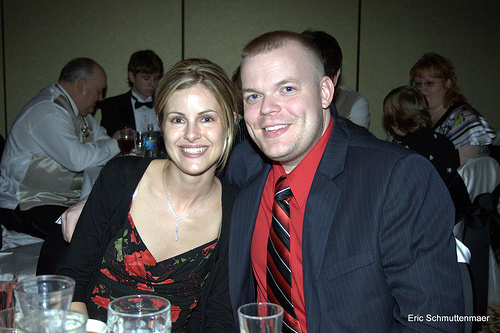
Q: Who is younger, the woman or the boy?
A: The boy is younger than the woman.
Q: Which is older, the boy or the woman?
A: The woman is older than the boy.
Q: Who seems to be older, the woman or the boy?
A: The woman is older than the boy.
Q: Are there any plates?
A: No, there are no plates.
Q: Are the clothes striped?
A: Yes, the clothes are striped.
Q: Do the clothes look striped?
A: Yes, the clothes are striped.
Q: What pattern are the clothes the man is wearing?
A: The clothes are striped.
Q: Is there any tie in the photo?
A: Yes, there is a tie.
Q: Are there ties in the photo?
A: Yes, there is a tie.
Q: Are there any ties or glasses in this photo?
A: Yes, there is a tie.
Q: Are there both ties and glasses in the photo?
A: Yes, there are both a tie and glasses.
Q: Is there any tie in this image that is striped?
A: Yes, there is a striped tie.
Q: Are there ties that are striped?
A: Yes, there is a tie that is striped.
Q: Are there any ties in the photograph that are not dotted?
A: Yes, there is a striped tie.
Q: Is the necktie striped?
A: Yes, the necktie is striped.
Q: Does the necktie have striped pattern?
A: Yes, the necktie is striped.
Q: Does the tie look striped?
A: Yes, the tie is striped.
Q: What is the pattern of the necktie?
A: The necktie is striped.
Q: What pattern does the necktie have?
A: The necktie has striped pattern.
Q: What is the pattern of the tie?
A: The necktie is striped.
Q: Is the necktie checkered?
A: No, the necktie is striped.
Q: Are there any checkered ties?
A: No, there is a tie but it is striped.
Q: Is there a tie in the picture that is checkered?
A: No, there is a tie but it is striped.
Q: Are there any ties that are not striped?
A: No, there is a tie but it is striped.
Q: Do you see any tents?
A: No, there are no tents.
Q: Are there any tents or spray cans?
A: No, there are no tents or spray cans.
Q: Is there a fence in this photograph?
A: No, there are no fences.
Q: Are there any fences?
A: No, there are no fences.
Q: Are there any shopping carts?
A: No, there are no shopping carts.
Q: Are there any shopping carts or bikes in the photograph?
A: No, there are no shopping carts or bikes.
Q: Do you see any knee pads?
A: No, there are no knee pads.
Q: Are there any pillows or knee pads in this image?
A: No, there are no knee pads or pillows.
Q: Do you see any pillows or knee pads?
A: No, there are no knee pads or pillows.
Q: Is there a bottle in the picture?
A: Yes, there is a bottle.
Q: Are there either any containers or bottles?
A: Yes, there is a bottle.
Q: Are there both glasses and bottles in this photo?
A: Yes, there are both a bottle and glasses.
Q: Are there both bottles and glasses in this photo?
A: Yes, there are both a bottle and glasses.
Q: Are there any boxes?
A: No, there are no boxes.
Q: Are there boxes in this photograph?
A: No, there are no boxes.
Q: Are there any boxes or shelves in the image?
A: No, there are no boxes or shelves.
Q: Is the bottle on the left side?
A: Yes, the bottle is on the left of the image.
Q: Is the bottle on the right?
A: No, the bottle is on the left of the image.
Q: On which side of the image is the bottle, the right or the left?
A: The bottle is on the left of the image.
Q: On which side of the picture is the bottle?
A: The bottle is on the left of the image.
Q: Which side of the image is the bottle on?
A: The bottle is on the left of the image.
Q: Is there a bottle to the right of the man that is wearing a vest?
A: Yes, there is a bottle to the right of the man.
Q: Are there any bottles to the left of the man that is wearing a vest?
A: No, the bottle is to the right of the man.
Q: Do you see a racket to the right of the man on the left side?
A: No, there is a bottle to the right of the man.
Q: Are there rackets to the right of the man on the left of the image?
A: No, there is a bottle to the right of the man.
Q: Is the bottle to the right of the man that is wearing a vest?
A: Yes, the bottle is to the right of the man.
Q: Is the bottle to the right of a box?
A: No, the bottle is to the right of the man.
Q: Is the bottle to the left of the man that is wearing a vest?
A: No, the bottle is to the right of the man.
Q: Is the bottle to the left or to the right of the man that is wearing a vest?
A: The bottle is to the right of the man.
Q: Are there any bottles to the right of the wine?
A: Yes, there is a bottle to the right of the wine.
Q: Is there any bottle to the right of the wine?
A: Yes, there is a bottle to the right of the wine.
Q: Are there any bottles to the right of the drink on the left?
A: Yes, there is a bottle to the right of the wine.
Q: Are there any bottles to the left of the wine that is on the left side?
A: No, the bottle is to the right of the wine.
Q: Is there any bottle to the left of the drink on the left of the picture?
A: No, the bottle is to the right of the wine.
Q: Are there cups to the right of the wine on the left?
A: No, there is a bottle to the right of the wine.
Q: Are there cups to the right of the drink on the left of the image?
A: No, there is a bottle to the right of the wine.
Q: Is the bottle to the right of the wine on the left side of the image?
A: Yes, the bottle is to the right of the wine.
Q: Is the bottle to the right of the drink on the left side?
A: Yes, the bottle is to the right of the wine.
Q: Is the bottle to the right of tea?
A: No, the bottle is to the right of the wine.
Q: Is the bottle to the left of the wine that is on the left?
A: No, the bottle is to the right of the wine.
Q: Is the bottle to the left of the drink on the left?
A: No, the bottle is to the right of the wine.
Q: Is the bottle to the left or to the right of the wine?
A: The bottle is to the right of the wine.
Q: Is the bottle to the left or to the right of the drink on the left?
A: The bottle is to the right of the wine.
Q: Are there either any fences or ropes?
A: No, there are no fences or ropes.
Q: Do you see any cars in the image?
A: No, there are no cars.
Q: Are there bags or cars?
A: No, there are no cars or bags.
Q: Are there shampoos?
A: No, there are no shampoos.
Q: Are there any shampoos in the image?
A: No, there are no shampoos.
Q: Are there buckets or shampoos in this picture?
A: No, there are no shampoos or buckets.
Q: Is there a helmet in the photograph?
A: No, there are no helmets.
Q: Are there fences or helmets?
A: No, there are no helmets or fences.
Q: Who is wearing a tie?
A: The man is wearing a tie.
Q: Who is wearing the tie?
A: The man is wearing a tie.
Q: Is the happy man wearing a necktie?
A: Yes, the man is wearing a necktie.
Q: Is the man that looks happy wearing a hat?
A: No, the man is wearing a necktie.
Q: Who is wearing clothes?
A: The man is wearing clothes.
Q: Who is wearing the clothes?
A: The man is wearing clothes.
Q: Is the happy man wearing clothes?
A: Yes, the man is wearing clothes.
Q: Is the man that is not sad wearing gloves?
A: No, the man is wearing clothes.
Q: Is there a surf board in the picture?
A: No, there are no surfboards.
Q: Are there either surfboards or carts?
A: No, there are no surfboards or carts.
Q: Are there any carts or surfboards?
A: No, there are no surfboards or carts.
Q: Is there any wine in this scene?
A: Yes, there is wine.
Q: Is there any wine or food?
A: Yes, there is wine.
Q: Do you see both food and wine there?
A: No, there is wine but no food.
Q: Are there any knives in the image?
A: No, there are no knives.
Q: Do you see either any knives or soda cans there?
A: No, there are no knives or soda cans.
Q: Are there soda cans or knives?
A: No, there are no knives or soda cans.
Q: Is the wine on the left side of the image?
A: Yes, the wine is on the left of the image.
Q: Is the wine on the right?
A: No, the wine is on the left of the image.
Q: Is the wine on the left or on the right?
A: The wine is on the left of the image.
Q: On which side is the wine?
A: The wine is on the left of the image.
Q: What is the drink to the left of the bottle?
A: The drink is wine.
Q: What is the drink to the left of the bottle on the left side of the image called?
A: The drink is wine.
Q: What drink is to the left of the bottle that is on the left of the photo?
A: The drink is wine.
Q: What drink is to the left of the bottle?
A: The drink is wine.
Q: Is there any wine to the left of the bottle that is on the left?
A: Yes, there is wine to the left of the bottle.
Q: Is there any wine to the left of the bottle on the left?
A: Yes, there is wine to the left of the bottle.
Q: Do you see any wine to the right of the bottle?
A: No, the wine is to the left of the bottle.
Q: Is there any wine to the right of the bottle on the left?
A: No, the wine is to the left of the bottle.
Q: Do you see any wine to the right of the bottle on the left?
A: No, the wine is to the left of the bottle.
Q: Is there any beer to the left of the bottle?
A: No, there is wine to the left of the bottle.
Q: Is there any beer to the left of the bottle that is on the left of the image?
A: No, there is wine to the left of the bottle.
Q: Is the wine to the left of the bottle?
A: Yes, the wine is to the left of the bottle.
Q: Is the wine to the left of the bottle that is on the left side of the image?
A: Yes, the wine is to the left of the bottle.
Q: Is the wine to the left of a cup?
A: No, the wine is to the left of the bottle.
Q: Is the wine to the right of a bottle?
A: No, the wine is to the left of a bottle.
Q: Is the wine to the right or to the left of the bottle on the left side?
A: The wine is to the left of the bottle.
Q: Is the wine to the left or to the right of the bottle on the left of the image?
A: The wine is to the left of the bottle.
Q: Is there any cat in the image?
A: No, there are no cats.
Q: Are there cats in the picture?
A: No, there are no cats.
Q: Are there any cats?
A: No, there are no cats.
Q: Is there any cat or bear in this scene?
A: No, there are no cats or bears.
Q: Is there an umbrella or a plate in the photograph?
A: No, there are no plates or umbrellas.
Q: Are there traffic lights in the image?
A: No, there are no traffic lights.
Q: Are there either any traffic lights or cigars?
A: No, there are no traffic lights or cigars.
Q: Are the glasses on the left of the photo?
A: Yes, the glasses are on the left of the image.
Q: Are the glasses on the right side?
A: No, the glasses are on the left of the image.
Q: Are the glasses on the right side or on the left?
A: The glasses are on the left of the image.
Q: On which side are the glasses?
A: The glasses are on the left of the image.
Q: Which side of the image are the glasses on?
A: The glasses are on the left of the image.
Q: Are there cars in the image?
A: No, there are no cars.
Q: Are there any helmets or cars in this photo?
A: No, there are no cars or helmets.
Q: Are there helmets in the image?
A: No, there are no helmets.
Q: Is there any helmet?
A: No, there are no helmets.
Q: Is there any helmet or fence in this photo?
A: No, there are no helmets or fences.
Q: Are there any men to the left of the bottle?
A: Yes, there is a man to the left of the bottle.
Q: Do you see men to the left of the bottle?
A: Yes, there is a man to the left of the bottle.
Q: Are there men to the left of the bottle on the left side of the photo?
A: Yes, there is a man to the left of the bottle.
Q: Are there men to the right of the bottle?
A: No, the man is to the left of the bottle.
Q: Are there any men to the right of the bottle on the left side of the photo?
A: No, the man is to the left of the bottle.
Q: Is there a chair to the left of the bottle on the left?
A: No, there is a man to the left of the bottle.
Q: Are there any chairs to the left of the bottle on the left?
A: No, there is a man to the left of the bottle.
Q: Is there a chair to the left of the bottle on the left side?
A: No, there is a man to the left of the bottle.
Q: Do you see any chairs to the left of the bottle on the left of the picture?
A: No, there is a man to the left of the bottle.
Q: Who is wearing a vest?
A: The man is wearing a vest.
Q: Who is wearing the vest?
A: The man is wearing a vest.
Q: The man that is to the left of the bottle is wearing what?
A: The man is wearing a vest.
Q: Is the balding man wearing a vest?
A: Yes, the man is wearing a vest.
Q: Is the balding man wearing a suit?
A: No, the man is wearing a vest.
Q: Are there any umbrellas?
A: No, there are no umbrellas.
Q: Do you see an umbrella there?
A: No, there are no umbrellas.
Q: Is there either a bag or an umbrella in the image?
A: No, there are no umbrellas or bags.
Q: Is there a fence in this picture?
A: No, there are no fences.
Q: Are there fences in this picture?
A: No, there are no fences.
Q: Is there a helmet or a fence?
A: No, there are no fences or helmets.